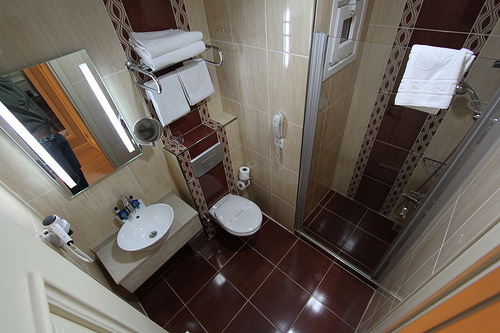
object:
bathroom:
[1, 0, 499, 332]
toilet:
[207, 192, 264, 237]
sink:
[116, 203, 175, 252]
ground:
[303, 186, 405, 276]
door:
[293, 30, 498, 280]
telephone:
[270, 110, 286, 165]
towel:
[393, 44, 477, 115]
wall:
[73, 6, 292, 197]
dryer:
[41, 212, 94, 264]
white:
[413, 60, 459, 97]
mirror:
[133, 116, 165, 143]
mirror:
[0, 48, 142, 200]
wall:
[247, 166, 328, 204]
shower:
[292, 0, 499, 279]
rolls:
[237, 165, 252, 181]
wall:
[0, 171, 118, 285]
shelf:
[124, 44, 224, 95]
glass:
[303, 35, 500, 278]